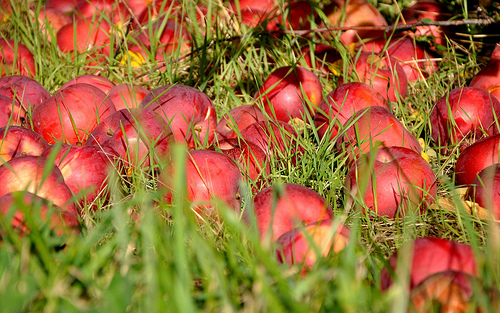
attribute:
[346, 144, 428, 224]
red apples — in a field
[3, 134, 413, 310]
grass — long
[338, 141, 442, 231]
apples — red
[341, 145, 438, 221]
apples — ripe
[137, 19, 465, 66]
twig — in the grass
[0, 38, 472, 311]
apples — on the ground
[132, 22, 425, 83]
stick — on the ground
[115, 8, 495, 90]
branch — small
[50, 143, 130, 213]
apple — red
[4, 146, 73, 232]
apple — red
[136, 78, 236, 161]
apple — red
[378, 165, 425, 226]
apple — red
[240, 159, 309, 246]
apple — red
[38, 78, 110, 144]
apple — red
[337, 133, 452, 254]
apple — red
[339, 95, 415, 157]
apple — red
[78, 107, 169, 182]
apple — red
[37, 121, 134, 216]
apple — red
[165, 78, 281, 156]
apple — red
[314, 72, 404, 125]
apple — red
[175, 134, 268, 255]
apple — red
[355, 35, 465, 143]
apple — red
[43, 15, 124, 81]
apple — red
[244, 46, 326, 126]
apple — red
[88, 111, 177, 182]
apple — red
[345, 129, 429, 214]
apple — red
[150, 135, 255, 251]
apple — red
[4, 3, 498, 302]
apples — red